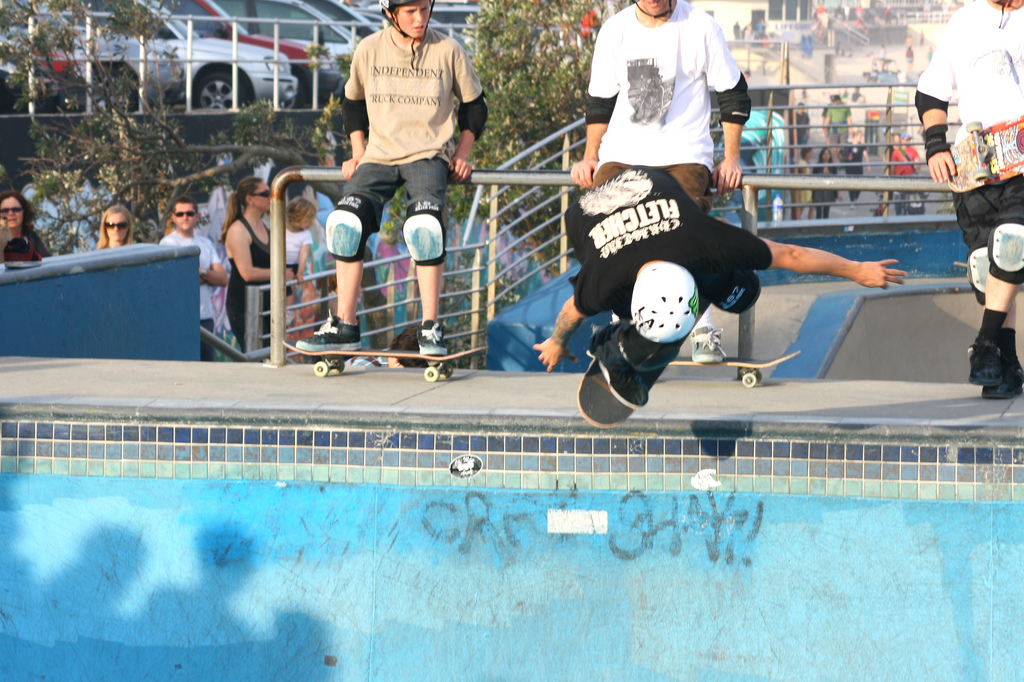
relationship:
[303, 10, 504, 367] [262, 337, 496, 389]
boy on skateboard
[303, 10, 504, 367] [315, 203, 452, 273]
boy wears knee pads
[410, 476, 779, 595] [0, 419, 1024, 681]
graffiti on pool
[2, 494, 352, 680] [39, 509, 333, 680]
people has reflection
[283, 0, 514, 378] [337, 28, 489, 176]
boy has shirt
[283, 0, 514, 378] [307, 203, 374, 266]
boy has knee pad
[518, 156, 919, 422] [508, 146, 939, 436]
skateboarder performs trick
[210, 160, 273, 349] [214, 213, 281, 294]
woman wears tank top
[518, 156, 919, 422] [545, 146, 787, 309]
skateboarder wears shirt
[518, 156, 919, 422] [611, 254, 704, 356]
skateboarder wearing helmet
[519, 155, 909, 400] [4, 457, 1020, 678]
skateboarder on ramp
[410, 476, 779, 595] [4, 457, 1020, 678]
graffiti on ramp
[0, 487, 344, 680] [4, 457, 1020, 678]
reflection are on ramp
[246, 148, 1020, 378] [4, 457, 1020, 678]
railing on top of ramp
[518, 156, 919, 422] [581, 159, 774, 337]
skateboarder wearing shirt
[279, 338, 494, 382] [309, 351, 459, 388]
skateboards has wheels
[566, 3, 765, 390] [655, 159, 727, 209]
skateboarder wearing shorts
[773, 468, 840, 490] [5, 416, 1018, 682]
brick on tiles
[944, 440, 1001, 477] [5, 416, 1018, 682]
brick on tiles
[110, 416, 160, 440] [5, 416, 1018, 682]
brick on tiles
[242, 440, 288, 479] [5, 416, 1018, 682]
brick on tiles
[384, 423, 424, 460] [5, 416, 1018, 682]
brick on tiles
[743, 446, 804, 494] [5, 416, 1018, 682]
brick on tiles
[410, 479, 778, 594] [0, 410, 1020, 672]
graffiti on pool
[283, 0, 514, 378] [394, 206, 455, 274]
boy wearing knee pad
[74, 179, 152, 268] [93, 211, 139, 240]
woman wearing sunglasses